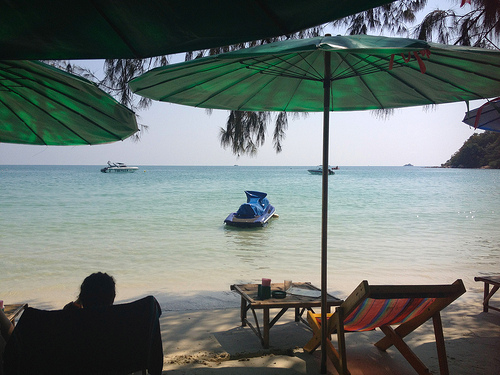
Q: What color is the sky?
A: Blue.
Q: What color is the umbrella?
A: Green.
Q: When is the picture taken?
A: Daytime.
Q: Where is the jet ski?
A: Water.